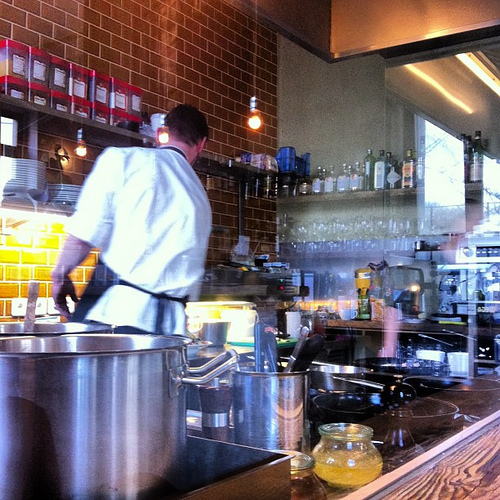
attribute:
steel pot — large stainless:
[0, 333, 192, 498]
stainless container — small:
[186, 353, 311, 463]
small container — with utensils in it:
[232, 322, 307, 466]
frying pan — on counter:
[310, 385, 387, 420]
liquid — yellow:
[314, 455, 385, 489]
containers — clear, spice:
[0, 30, 149, 129]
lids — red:
[0, 35, 141, 131]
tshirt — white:
[69, 139, 211, 343]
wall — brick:
[4, 4, 322, 319]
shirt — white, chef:
[70, 143, 224, 339]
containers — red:
[3, 35, 151, 134]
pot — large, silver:
[3, 327, 204, 497]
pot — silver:
[4, 322, 248, 498]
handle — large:
[176, 332, 246, 395]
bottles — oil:
[297, 144, 422, 197]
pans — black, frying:
[312, 364, 462, 415]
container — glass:
[305, 417, 382, 490]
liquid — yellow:
[313, 451, 385, 487]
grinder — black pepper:
[378, 366, 425, 460]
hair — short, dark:
[159, 98, 215, 147]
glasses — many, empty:
[281, 212, 440, 261]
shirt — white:
[74, 141, 217, 348]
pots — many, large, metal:
[13, 306, 211, 497]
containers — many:
[10, 43, 166, 116]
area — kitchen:
[19, 15, 484, 420]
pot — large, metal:
[18, 274, 238, 498]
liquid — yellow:
[300, 404, 359, 498]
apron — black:
[68, 231, 218, 319]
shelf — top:
[300, 168, 410, 215]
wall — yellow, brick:
[15, 228, 83, 301]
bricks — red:
[143, 6, 287, 87]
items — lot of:
[242, 300, 455, 456]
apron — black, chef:
[75, 265, 125, 305]